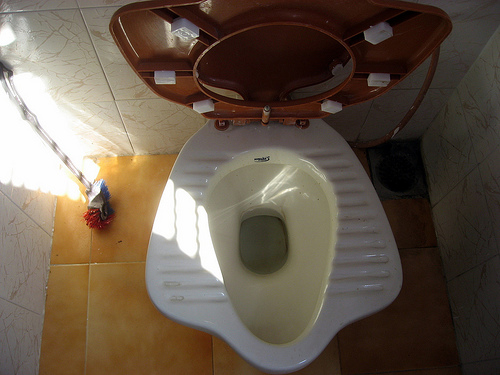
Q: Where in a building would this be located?
A: Bathroom.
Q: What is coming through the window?
A: Sunlight.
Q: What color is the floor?
A: Gold.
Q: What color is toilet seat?
A: Brown.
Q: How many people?
A: No people.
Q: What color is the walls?
A: White.